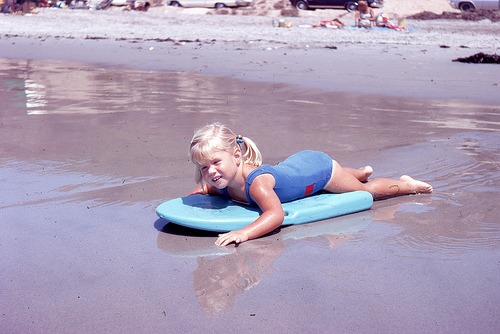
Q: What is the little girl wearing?
A: Swimsuit.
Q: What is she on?
A: Paddleboard.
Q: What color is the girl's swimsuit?
A: Blue.